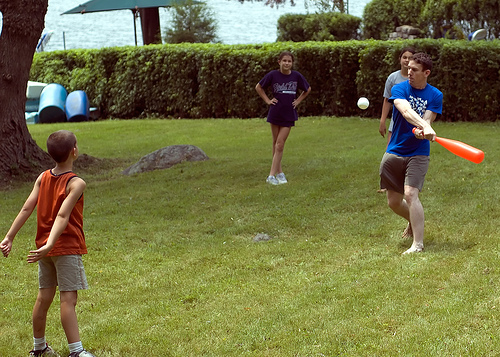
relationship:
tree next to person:
[4, 17, 76, 125] [16, 149, 136, 294]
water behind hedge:
[36, 5, 390, 56] [20, 34, 498, 119]